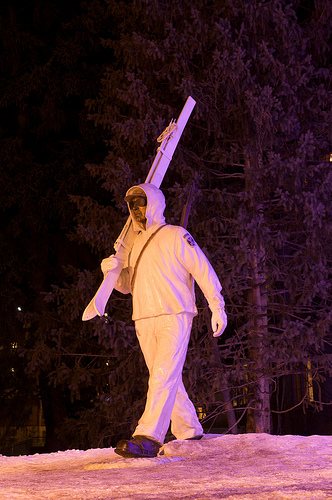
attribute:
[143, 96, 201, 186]
skis — white, strapped together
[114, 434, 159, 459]
boots — black, ski boots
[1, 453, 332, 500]
snow — white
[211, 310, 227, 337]
ski gloves — white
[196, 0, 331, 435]
pine trees — green, building, pine trees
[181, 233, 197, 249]
patch — blue, yellow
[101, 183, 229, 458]
man — walking, skier, marching, soldier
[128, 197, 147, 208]
sunglasses — black, ski goggles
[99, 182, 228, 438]
outfit — shiny, white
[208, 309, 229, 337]
gloves — white